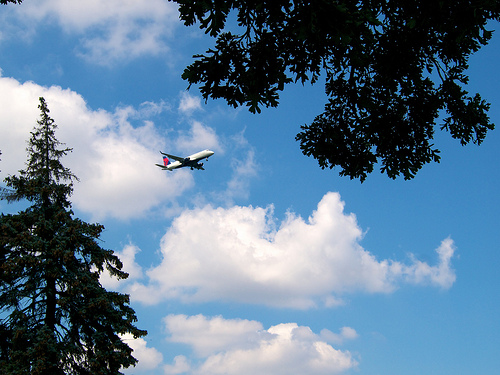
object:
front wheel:
[204, 156, 208, 162]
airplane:
[154, 149, 218, 171]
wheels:
[188, 165, 197, 172]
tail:
[160, 151, 171, 169]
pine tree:
[0, 95, 148, 374]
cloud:
[124, 190, 460, 308]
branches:
[56, 321, 85, 349]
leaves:
[16, 333, 23, 341]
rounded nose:
[204, 150, 216, 158]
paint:
[162, 155, 171, 164]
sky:
[0, 0, 500, 374]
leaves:
[429, 141, 435, 150]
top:
[31, 95, 55, 137]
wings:
[159, 149, 191, 164]